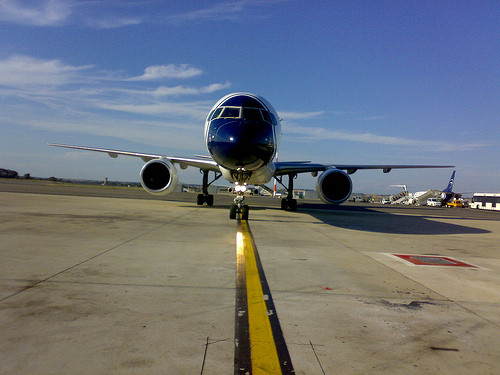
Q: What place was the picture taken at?
A: It was taken at the road.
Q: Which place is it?
A: It is a road.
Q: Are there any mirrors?
A: No, there are no mirrors.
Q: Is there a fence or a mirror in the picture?
A: No, there are no mirrors or fences.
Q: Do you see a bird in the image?
A: No, there are no birds.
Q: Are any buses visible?
A: Yes, there is a bus.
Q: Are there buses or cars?
A: Yes, there is a bus.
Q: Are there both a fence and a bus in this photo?
A: No, there is a bus but no fences.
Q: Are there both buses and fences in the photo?
A: No, there is a bus but no fences.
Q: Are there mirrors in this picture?
A: No, there are no mirrors.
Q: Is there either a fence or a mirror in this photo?
A: No, there are no mirrors or fences.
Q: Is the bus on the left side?
A: No, the bus is on the right of the image.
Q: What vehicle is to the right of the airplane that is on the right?
A: The vehicle is a bus.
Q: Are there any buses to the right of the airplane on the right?
A: Yes, there is a bus to the right of the plane.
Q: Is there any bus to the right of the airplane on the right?
A: Yes, there is a bus to the right of the plane.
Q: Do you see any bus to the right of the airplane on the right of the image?
A: Yes, there is a bus to the right of the plane.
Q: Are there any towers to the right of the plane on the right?
A: No, there is a bus to the right of the plane.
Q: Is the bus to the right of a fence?
A: No, the bus is to the right of the airplane.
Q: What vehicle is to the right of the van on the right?
A: The vehicle is a bus.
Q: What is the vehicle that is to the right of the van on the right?
A: The vehicle is a bus.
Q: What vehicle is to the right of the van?
A: The vehicle is a bus.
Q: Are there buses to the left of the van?
A: No, the bus is to the right of the van.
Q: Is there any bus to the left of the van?
A: No, the bus is to the right of the van.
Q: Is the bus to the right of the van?
A: Yes, the bus is to the right of the van.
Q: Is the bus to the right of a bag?
A: No, the bus is to the right of the van.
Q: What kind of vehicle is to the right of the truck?
A: The vehicle is a bus.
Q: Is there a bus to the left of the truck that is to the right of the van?
A: No, the bus is to the right of the truck.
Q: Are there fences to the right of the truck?
A: No, there is a bus to the right of the truck.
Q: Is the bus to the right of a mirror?
A: No, the bus is to the right of the truck.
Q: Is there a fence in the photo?
A: No, there are no fences.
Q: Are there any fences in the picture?
A: No, there are no fences.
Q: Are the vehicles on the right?
A: Yes, the vehicles are on the right of the image.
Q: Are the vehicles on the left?
A: No, the vehicles are on the right of the image.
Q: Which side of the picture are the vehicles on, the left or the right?
A: The vehicles are on the right of the image.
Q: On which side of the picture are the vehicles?
A: The vehicles are on the right of the image.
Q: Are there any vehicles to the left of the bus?
A: Yes, there are vehicles to the left of the bus.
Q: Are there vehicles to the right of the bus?
A: No, the vehicles are to the left of the bus.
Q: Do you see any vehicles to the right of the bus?
A: No, the vehicles are to the left of the bus.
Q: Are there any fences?
A: No, there are no fences.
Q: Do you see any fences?
A: No, there are no fences.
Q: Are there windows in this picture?
A: Yes, there are windows.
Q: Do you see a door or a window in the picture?
A: Yes, there are windows.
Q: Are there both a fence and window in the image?
A: No, there are windows but no fences.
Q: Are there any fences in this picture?
A: No, there are no fences.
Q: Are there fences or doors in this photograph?
A: No, there are no fences or doors.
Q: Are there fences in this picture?
A: No, there are no fences.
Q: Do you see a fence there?
A: No, there are no fences.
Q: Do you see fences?
A: No, there are no fences.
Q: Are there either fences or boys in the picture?
A: No, there are no fences or boys.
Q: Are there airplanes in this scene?
A: Yes, there is an airplane.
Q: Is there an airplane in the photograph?
A: Yes, there is an airplane.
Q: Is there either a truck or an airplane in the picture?
A: Yes, there is an airplane.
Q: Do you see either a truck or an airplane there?
A: Yes, there is an airplane.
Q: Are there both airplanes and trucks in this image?
A: Yes, there are both an airplane and a truck.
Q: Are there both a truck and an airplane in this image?
A: Yes, there are both an airplane and a truck.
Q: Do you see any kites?
A: No, there are no kites.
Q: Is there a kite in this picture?
A: No, there are no kites.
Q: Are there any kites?
A: No, there are no kites.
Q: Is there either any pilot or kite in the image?
A: No, there are no kites or pilots.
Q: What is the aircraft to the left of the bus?
A: The aircraft is an airplane.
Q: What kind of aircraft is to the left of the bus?
A: The aircraft is an airplane.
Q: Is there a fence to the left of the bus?
A: No, there is an airplane to the left of the bus.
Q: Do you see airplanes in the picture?
A: Yes, there is an airplane.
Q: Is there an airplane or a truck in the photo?
A: Yes, there is an airplane.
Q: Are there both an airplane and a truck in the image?
A: Yes, there are both an airplane and a truck.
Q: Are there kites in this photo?
A: No, there are no kites.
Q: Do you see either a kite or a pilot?
A: No, there are no kites or pilots.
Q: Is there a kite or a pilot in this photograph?
A: No, there are no kites or pilots.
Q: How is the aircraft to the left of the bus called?
A: The aircraft is an airplane.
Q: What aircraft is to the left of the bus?
A: The aircraft is an airplane.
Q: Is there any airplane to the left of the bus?
A: Yes, there is an airplane to the left of the bus.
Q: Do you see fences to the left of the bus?
A: No, there is an airplane to the left of the bus.